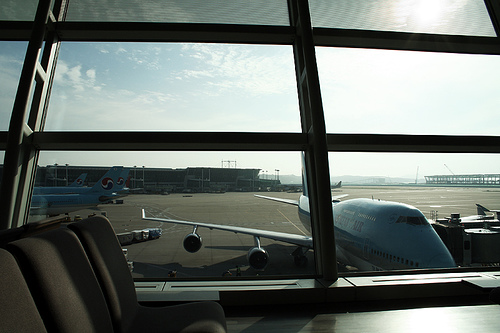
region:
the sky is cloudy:
[39, 45, 266, 121]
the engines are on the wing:
[152, 201, 288, 283]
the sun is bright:
[342, 0, 471, 40]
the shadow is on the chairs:
[2, 188, 215, 331]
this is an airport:
[131, 138, 453, 278]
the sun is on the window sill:
[361, 252, 459, 289]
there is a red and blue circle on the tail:
[81, 157, 126, 208]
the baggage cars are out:
[110, 222, 179, 247]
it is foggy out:
[326, 161, 428, 195]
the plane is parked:
[202, 162, 473, 291]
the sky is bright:
[82, 64, 249, 116]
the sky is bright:
[100, 48, 231, 102]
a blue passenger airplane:
[287, 182, 461, 272]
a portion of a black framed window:
[19, 30, 314, 161]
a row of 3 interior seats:
[3, 226, 132, 326]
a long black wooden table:
[222, 303, 487, 326]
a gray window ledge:
[141, 277, 293, 301]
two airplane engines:
[171, 228, 278, 263]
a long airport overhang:
[422, 162, 497, 190]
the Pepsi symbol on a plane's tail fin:
[90, 164, 120, 193]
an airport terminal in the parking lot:
[100, 155, 271, 192]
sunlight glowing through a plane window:
[362, 1, 489, 37]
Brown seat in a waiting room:
[76, 227, 225, 332]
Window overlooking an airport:
[40, 152, 316, 278]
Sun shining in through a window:
[388, 1, 476, 30]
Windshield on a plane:
[398, 213, 428, 225]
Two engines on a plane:
[171, 224, 275, 274]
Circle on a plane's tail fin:
[100, 179, 117, 190]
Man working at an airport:
[167, 267, 184, 279]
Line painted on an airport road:
[271, 202, 309, 257]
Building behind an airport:
[421, 173, 499, 193]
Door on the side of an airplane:
[362, 238, 372, 260]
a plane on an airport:
[277, 142, 474, 280]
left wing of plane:
[127, 201, 332, 261]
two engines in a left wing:
[174, 217, 274, 275]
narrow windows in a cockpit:
[380, 201, 442, 239]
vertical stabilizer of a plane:
[82, 156, 142, 211]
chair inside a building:
[6, 205, 249, 332]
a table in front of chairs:
[289, 295, 499, 330]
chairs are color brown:
[1, 209, 236, 331]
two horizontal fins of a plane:
[237, 184, 357, 209]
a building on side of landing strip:
[48, 156, 289, 196]